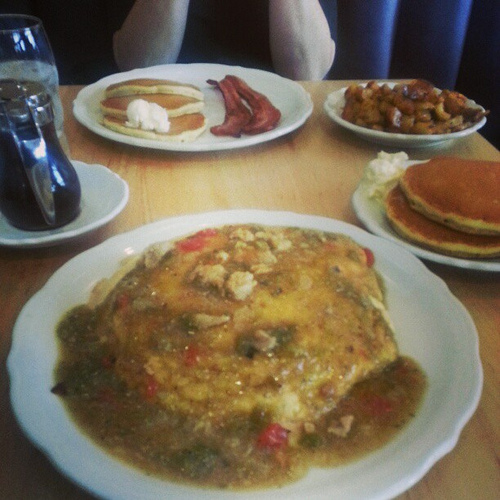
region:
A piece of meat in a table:
[379, 104, 403, 124]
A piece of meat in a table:
[357, 83, 364, 100]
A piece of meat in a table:
[438, 84, 453, 109]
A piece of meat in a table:
[368, 78, 380, 88]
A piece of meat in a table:
[409, 117, 430, 132]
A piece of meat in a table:
[465, 107, 483, 119]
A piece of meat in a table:
[358, 85, 369, 101]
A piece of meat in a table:
[389, 92, 411, 113]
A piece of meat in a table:
[376, 98, 391, 113]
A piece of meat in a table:
[341, 97, 359, 117]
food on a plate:
[111, 222, 371, 462]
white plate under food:
[412, 285, 480, 376]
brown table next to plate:
[446, 431, 496, 492]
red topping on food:
[238, 406, 303, 458]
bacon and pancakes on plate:
[105, 48, 280, 169]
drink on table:
[0, 12, 114, 181]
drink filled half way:
[14, 3, 114, 220]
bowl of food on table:
[338, 58, 478, 163]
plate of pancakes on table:
[344, 142, 492, 241]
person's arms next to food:
[103, 12, 350, 85]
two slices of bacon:
[210, 72, 281, 139]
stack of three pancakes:
[102, 73, 209, 138]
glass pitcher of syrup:
[0, 82, 86, 227]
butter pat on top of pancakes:
[120, 95, 172, 134]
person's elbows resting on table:
[95, 0, 345, 87]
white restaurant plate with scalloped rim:
[10, 212, 482, 499]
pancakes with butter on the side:
[350, 147, 498, 262]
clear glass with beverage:
[0, 14, 62, 134]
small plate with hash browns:
[327, 76, 489, 154]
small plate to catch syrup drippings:
[0, 156, 130, 246]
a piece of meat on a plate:
[382, 104, 402, 125]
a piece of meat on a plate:
[353, 84, 369, 95]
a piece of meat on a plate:
[446, 94, 463, 115]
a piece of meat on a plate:
[406, 82, 421, 97]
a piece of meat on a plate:
[410, 119, 432, 136]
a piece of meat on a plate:
[394, 100, 419, 117]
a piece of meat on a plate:
[368, 107, 377, 123]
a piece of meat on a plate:
[398, 85, 424, 103]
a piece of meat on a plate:
[353, 100, 368, 120]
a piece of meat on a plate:
[346, 105, 358, 117]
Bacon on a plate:
[197, 74, 307, 160]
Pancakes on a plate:
[95, 76, 222, 146]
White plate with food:
[70, 64, 325, 169]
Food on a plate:
[111, 234, 391, 481]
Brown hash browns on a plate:
[338, 69, 466, 162]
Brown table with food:
[93, 124, 282, 225]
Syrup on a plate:
[5, 77, 107, 274]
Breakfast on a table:
[83, 66, 490, 306]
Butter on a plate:
[349, 143, 414, 197]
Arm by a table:
[267, 5, 349, 91]